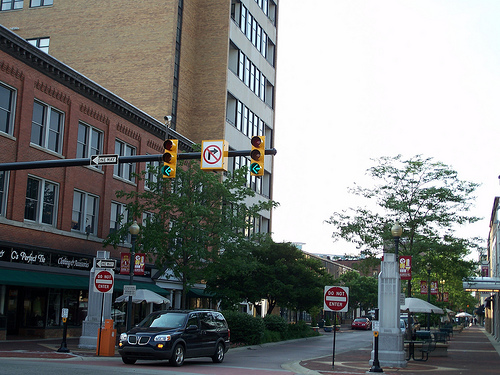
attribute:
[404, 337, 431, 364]
table — picnic table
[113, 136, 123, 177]
window — glass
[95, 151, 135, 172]
sign — One Way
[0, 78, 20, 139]
window — glass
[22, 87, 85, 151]
window — glass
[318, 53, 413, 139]
sky — white, bright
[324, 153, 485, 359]
tree — large, green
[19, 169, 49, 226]
window — glass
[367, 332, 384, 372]
post — green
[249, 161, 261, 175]
arrow — green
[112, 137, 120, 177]
window — glass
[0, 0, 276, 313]
brown building — tall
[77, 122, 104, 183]
window — glass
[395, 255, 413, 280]
sign — red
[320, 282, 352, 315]
sign — Do Not Enter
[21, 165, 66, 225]
window — glass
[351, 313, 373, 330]
car — red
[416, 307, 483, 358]
sidewalk — part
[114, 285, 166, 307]
umbrella — white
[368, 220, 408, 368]
statue — tall